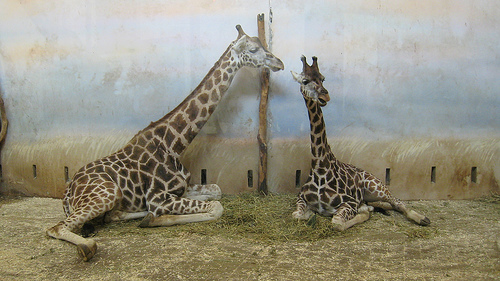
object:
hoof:
[76, 242, 94, 261]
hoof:
[136, 211, 156, 227]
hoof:
[103, 206, 116, 224]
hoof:
[417, 212, 431, 224]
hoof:
[359, 203, 374, 221]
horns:
[235, 24, 247, 36]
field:
[0, 200, 499, 277]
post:
[382, 165, 392, 187]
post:
[429, 163, 437, 180]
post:
[470, 163, 479, 184]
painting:
[8, 13, 76, 200]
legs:
[44, 176, 122, 262]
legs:
[357, 169, 431, 225]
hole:
[30, 164, 37, 180]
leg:
[138, 196, 223, 230]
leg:
[180, 182, 219, 199]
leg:
[106, 208, 145, 218]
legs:
[332, 203, 372, 232]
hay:
[213, 188, 335, 240]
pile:
[213, 180, 339, 247]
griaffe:
[288, 52, 435, 230]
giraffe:
[294, 56, 430, 241]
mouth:
[318, 97, 329, 105]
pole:
[251, 8, 277, 192]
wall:
[2, 2, 498, 196]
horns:
[300, 55, 309, 67]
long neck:
[306, 102, 336, 167]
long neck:
[150, 57, 251, 150]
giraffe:
[44, 23, 287, 261]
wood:
[253, 91, 270, 181]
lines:
[30, 160, 479, 185]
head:
[229, 24, 288, 74]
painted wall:
[398, 0, 486, 200]